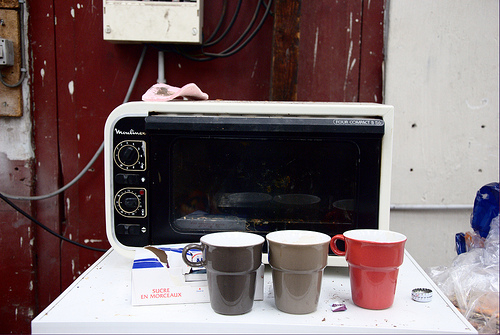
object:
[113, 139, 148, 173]
knob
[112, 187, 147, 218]
knob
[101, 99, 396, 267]
microwave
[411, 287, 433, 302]
cap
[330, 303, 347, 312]
granules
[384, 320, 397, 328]
granules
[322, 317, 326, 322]
granules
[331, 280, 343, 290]
granules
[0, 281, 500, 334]
ground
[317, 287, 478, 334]
edge table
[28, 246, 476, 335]
counter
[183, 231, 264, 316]
brown mug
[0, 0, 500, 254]
wall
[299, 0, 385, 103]
paint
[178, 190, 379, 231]
reflection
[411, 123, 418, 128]
hole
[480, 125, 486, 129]
hole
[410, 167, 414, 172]
hole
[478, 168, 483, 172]
hole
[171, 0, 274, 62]
cords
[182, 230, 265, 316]
rocks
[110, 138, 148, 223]
dials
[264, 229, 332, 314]
coffee cups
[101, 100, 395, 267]
dryer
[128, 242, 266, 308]
box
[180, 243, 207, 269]
handle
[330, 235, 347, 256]
handle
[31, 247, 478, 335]
table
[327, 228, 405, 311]
cup